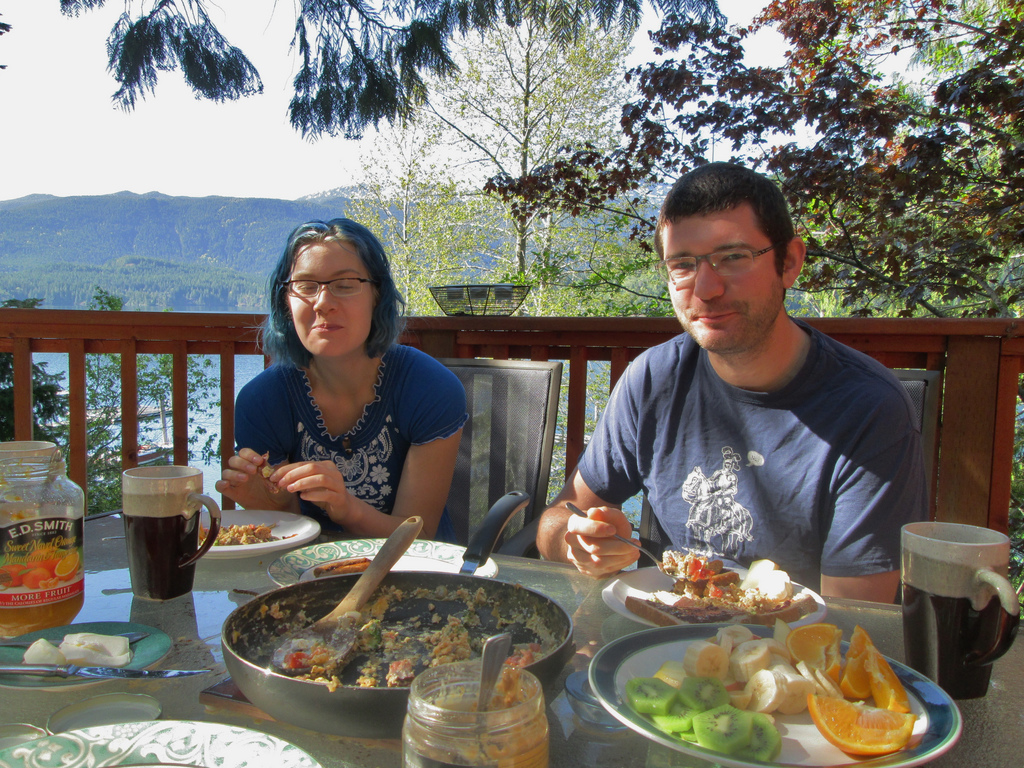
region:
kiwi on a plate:
[686, 697, 773, 764]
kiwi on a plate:
[621, 662, 675, 720]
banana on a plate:
[715, 618, 772, 669]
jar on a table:
[403, 621, 590, 740]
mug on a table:
[882, 507, 1019, 619]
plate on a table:
[14, 608, 210, 701]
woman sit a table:
[248, 210, 457, 463]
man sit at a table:
[599, 146, 881, 524]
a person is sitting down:
[210, 217, 483, 534]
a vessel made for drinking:
[896, 516, 1021, 706]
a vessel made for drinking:
[122, 455, 222, 608]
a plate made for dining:
[590, 593, 945, 767]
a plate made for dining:
[600, 543, 822, 651]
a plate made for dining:
[145, 476, 322, 584]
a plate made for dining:
[251, 514, 498, 592]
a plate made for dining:
[33, 720, 302, 766]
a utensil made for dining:
[11, 655, 214, 706]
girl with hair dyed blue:
[223, 212, 468, 546]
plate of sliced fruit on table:
[588, 593, 968, 767]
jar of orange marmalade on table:
[0, 432, 89, 644]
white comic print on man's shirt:
[678, 429, 773, 566]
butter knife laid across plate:
[0, 654, 215, 686]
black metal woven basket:
[427, 279, 532, 318]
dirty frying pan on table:
[213, 477, 578, 740]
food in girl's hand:
[253, 445, 283, 493]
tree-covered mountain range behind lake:
[1, 183, 276, 314]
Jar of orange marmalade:
[2, 433, 85, 629]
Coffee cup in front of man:
[894, 519, 1019, 704]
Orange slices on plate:
[787, 620, 918, 763]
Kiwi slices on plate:
[627, 673, 782, 762]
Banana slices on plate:
[697, 619, 806, 709]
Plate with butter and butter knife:
[2, 619, 211, 695]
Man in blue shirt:
[536, 159, 925, 589]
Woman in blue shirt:
[227, 221, 463, 528]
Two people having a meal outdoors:
[225, 160, 925, 607]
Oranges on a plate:
[809, 623, 923, 757]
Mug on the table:
[117, 453, 219, 606]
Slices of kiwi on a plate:
[625, 661, 780, 763]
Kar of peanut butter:
[401, 649, 550, 766]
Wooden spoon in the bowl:
[276, 498, 422, 673]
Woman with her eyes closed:
[219, 204, 470, 543]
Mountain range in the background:
[4, 176, 656, 306]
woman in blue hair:
[188, 189, 490, 545]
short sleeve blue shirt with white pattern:
[212, 353, 487, 524]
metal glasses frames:
[661, 237, 778, 277]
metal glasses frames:
[286, 274, 372, 307]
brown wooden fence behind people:
[4, 284, 1022, 597]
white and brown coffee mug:
[879, 503, 1022, 703]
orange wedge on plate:
[798, 688, 912, 762]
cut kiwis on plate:
[615, 644, 797, 766]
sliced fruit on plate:
[591, 620, 959, 766]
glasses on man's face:
[658, 162, 805, 355]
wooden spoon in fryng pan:
[221, 490, 573, 738]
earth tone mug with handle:
[898, 518, 1017, 699]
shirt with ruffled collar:
[235, 349, 467, 512]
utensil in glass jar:
[402, 633, 555, 764]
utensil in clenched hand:
[557, 501, 665, 578]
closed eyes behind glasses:
[285, 273, 378, 302]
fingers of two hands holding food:
[218, 447, 340, 515]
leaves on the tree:
[772, 118, 944, 305]